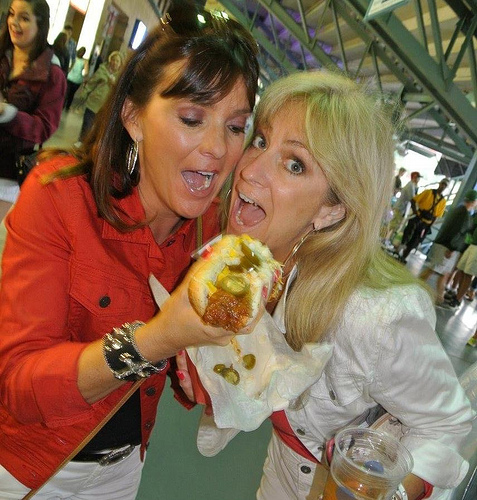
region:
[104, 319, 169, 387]
Black and silver studded bracelet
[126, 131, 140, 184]
Silver hoop earing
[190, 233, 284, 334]
Food in a hot dog bun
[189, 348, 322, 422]
White paper food wrapper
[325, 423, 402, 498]
Beverage in a clear disposable cup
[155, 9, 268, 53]
Sunglasses resting on woman's head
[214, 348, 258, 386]
Food spilled on white food wrapper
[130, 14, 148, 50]
Square window in side wall of building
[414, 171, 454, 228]
Person wearing a bright yellow shirt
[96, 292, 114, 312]
Black pocket button on red jean jacket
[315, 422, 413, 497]
Clear plastic cup of beer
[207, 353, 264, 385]
Pickles that have fallen off hot dog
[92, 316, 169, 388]
Leather and metal bracelet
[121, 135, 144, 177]
Silver hoop earring on woman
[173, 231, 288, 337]
Large condiment laden chili dog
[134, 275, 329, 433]
White paper hot dog wrapper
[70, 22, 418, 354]
Two women about to bite chili dog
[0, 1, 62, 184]
Woman in background ordering food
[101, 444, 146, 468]
Metal belt buckle on woman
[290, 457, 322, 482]
Pants button on woman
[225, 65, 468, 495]
Woman is holding a beverage.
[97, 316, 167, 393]
The bracelet is black and silver.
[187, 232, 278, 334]
Chili dog with chili, cheese, and jalapenos.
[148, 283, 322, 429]
Wrapper has jalapenos on it.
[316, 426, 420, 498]
Clear plastic cup with liquid.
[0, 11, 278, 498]
Woman is wearing a salmon colored shirt.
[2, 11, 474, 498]
Women are sharing a chili dog.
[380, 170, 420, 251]
Man is wearing tennis shoes.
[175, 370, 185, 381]
Fingernail polish is pink.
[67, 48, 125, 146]
Woman is wearing a coat.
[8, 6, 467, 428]
Two women with hot dog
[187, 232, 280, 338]
Chili cheese hot dog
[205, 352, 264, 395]
Jalepenos on white paper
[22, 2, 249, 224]
Brunette woman with sunglasses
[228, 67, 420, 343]
Blonde woman with open mouth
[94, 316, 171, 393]
Black bracelet with silver spikes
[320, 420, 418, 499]
Clear plastic cup with beer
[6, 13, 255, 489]
Brunette woman wearing red jacket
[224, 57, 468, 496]
Blonde woman in white jacket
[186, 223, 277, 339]
Chili cheese dog with jalpenos and onions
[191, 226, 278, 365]
A chili dog with jalapenos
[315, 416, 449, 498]
A cup of beer is in hand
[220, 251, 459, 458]
A woman is wearing a white jacket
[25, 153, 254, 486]
A woman is wearing a red jacket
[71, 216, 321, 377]
A woman is holding a hot dog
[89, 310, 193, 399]
A woman is wearing a black bracelet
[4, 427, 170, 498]
A woman is wearing white pants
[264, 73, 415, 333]
A woman has blonde hair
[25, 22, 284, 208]
A woman has dark hair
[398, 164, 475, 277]
Men are in the background